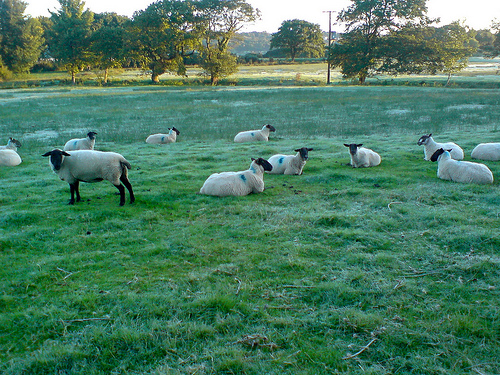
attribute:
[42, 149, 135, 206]
sheep — standing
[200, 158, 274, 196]
sheep — marked, spray painted, laying, resting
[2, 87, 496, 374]
grass — green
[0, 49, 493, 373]
field — green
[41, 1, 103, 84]
tree — green, tall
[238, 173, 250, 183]
mark — blue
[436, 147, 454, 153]
ears — raised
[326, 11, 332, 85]
pole — tall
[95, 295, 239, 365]
grass — clumped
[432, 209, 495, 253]
grass — clumped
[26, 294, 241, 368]
grass clump — big